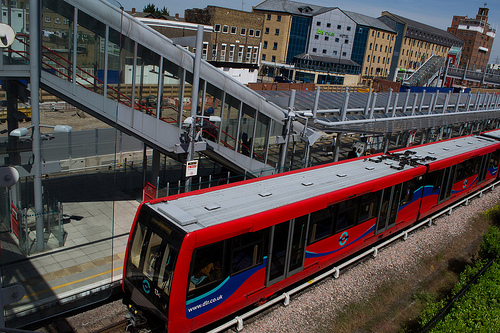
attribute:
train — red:
[130, 142, 480, 297]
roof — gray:
[145, 115, 498, 249]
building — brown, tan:
[253, 3, 398, 88]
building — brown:
[191, 3, 476, 96]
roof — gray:
[143, 126, 499, 232]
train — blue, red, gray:
[121, 130, 498, 332]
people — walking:
[177, 100, 282, 172]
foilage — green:
[411, 224, 499, 331]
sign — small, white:
[182, 159, 200, 179]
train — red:
[158, 221, 274, 323]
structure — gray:
[5, 0, 499, 174]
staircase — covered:
[30, 1, 284, 179]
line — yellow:
[21, 272, 124, 302]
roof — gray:
[349, 10, 400, 32]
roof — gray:
[396, 12, 458, 40]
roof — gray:
[253, 2, 330, 22]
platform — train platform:
[1, 1, 133, 304]